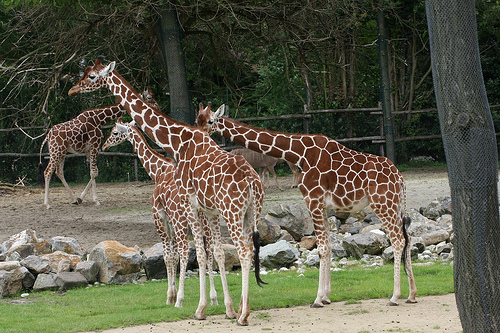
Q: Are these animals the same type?
A: Yes, all the animals are giraffes.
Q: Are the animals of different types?
A: No, all the animals are giraffes.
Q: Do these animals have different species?
A: No, all the animals are giraffes.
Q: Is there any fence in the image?
A: Yes, there is a fence.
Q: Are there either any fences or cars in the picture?
A: Yes, there is a fence.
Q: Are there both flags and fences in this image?
A: No, there is a fence but no flags.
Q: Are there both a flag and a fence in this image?
A: No, there is a fence but no flags.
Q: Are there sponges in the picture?
A: No, there are no sponges.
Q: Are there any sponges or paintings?
A: No, there are no sponges or paintings.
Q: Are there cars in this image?
A: No, there are no cars.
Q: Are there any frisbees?
A: No, there are no frisbees.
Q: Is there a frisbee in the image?
A: No, there are no frisbees.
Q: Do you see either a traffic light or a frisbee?
A: No, there are no frisbees or traffic lights.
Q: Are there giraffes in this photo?
A: Yes, there is a giraffe.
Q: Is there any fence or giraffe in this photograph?
A: Yes, there is a giraffe.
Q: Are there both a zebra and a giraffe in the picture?
A: No, there is a giraffe but no zebras.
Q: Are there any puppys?
A: No, there are no puppys.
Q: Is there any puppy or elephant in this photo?
A: No, there are no puppys or elephants.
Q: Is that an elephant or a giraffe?
A: That is a giraffe.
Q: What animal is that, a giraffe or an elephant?
A: That is a giraffe.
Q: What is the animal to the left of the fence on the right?
A: The animal is a giraffe.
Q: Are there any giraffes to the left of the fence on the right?
A: Yes, there is a giraffe to the left of the fence.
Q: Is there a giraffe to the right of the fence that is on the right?
A: No, the giraffe is to the left of the fence.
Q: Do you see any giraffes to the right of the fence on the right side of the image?
A: No, the giraffe is to the left of the fence.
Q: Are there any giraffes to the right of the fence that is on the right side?
A: No, the giraffe is to the left of the fence.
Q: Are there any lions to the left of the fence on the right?
A: No, there is a giraffe to the left of the fence.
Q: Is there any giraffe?
A: Yes, there is a giraffe.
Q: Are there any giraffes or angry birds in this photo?
A: Yes, there is a giraffe.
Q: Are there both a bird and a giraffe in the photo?
A: No, there is a giraffe but no birds.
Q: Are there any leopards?
A: No, there are no leopards.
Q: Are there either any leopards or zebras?
A: No, there are no leopards or zebras.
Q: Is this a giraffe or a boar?
A: This is a giraffe.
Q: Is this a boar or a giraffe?
A: This is a giraffe.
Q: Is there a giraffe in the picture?
A: Yes, there is a giraffe.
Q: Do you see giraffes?
A: Yes, there is a giraffe.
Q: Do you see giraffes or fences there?
A: Yes, there is a giraffe.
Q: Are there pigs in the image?
A: No, there are no pigs.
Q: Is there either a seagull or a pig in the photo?
A: No, there are no pigs or seagulls.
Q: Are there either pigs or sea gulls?
A: No, there are no pigs or sea gulls.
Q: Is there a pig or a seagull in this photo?
A: No, there are no pigs or seagulls.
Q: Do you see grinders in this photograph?
A: No, there are no grinders.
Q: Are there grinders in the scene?
A: No, there are no grinders.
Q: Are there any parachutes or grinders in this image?
A: No, there are no grinders or parachutes.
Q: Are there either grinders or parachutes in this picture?
A: No, there are no grinders or parachutes.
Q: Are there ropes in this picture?
A: No, there are no ropes.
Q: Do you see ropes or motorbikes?
A: No, there are no ropes or motorbikes.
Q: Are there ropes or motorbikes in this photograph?
A: No, there are no ropes or motorbikes.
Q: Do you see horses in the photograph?
A: No, there are no horses.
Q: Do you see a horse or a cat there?
A: No, there are no horses or cats.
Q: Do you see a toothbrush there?
A: No, there are no toothbrushes.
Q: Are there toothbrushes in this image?
A: No, there are no toothbrushes.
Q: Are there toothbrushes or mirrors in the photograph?
A: No, there are no toothbrushes or mirrors.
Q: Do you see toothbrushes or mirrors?
A: No, there are no toothbrushes or mirrors.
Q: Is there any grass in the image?
A: Yes, there is grass.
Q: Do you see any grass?
A: Yes, there is grass.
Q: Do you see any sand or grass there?
A: Yes, there is grass.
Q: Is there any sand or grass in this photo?
A: Yes, there is grass.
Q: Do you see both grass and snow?
A: No, there is grass but no snow.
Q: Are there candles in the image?
A: No, there are no candles.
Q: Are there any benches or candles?
A: No, there are no candles or benches.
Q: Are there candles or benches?
A: No, there are no candles or benches.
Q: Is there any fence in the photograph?
A: Yes, there is a fence.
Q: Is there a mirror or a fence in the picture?
A: Yes, there is a fence.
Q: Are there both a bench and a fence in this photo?
A: No, there is a fence but no benches.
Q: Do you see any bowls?
A: No, there are no bowls.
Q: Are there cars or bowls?
A: No, there are no bowls or cars.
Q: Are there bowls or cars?
A: No, there are no bowls or cars.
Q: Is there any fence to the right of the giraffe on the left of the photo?
A: Yes, there is a fence to the right of the giraffe.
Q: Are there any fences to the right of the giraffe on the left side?
A: Yes, there is a fence to the right of the giraffe.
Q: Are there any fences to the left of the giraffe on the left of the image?
A: No, the fence is to the right of the giraffe.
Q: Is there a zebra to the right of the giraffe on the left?
A: No, there is a fence to the right of the giraffe.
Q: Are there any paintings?
A: No, there are no paintings.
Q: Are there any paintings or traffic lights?
A: No, there are no paintings or traffic lights.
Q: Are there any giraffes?
A: Yes, there is a giraffe.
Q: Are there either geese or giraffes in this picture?
A: Yes, there is a giraffe.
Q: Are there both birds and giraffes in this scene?
A: No, there is a giraffe but no birds.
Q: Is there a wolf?
A: No, there are no wolves.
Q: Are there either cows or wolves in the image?
A: No, there are no wolves or cows.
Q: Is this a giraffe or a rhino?
A: This is a giraffe.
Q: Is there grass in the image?
A: Yes, there is grass.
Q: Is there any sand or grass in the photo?
A: Yes, there is grass.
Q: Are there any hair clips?
A: No, there are no hair clips.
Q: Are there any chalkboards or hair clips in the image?
A: No, there are no hair clips or chalkboards.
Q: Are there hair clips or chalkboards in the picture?
A: No, there are no hair clips or chalkboards.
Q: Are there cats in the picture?
A: No, there are no cats.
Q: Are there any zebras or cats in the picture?
A: No, there are no cats or zebras.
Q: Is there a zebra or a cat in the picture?
A: No, there are no cats or zebras.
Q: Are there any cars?
A: No, there are no cars.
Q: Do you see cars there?
A: No, there are no cars.